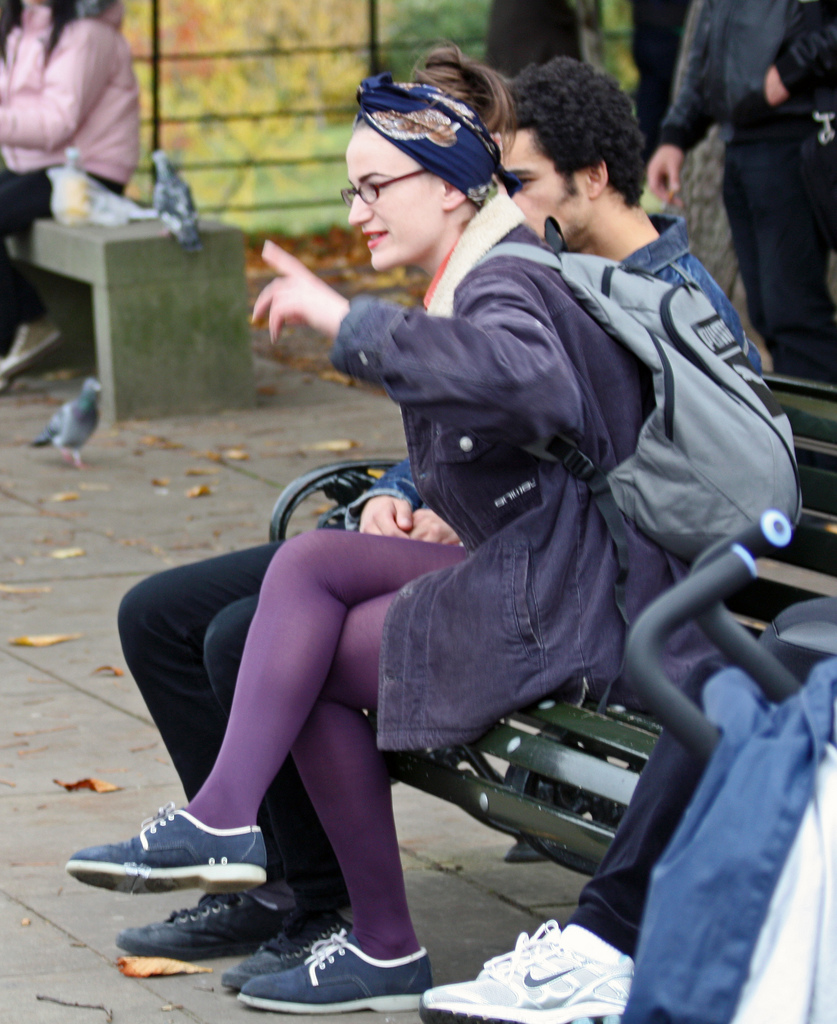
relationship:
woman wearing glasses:
[69, 41, 803, 1021] [339, 163, 429, 204]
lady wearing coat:
[0, 1, 143, 388] [0, 0, 142, 180]